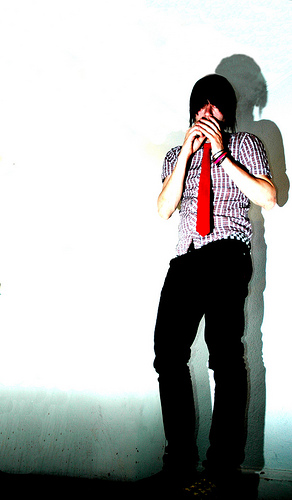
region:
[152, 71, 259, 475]
this is a boy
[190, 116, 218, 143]
these are the fingers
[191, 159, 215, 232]
this is the tie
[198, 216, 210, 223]
the tie is red in color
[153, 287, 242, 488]
these are the legs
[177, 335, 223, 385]
the legs are apart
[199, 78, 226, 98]
this is the hair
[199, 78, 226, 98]
the hair is black in color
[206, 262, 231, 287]
the trousers is black in color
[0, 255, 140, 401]
this is the wall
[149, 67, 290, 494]
person standing up alone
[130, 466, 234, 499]
shoes on the person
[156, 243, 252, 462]
pants on the person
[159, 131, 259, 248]
shirt on the person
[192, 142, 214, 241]
tie on the person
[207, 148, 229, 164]
bracelets on the person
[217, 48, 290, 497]
shadow of the person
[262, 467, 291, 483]
floor board person stands against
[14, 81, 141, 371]
wall person is leaning against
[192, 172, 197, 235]
buttons on person's shirt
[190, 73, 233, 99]
the hair is black in colour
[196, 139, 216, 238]
the tie is red in colour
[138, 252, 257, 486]
the pant is black in colour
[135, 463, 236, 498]
the shoe is black in colour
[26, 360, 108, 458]
the wall is white in colour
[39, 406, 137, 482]
the wall has red particles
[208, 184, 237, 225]
the shirt is stripped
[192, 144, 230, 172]
he has bangles on his hands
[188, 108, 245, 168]
his hands are on the mouth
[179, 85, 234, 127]
the hair is covering his face